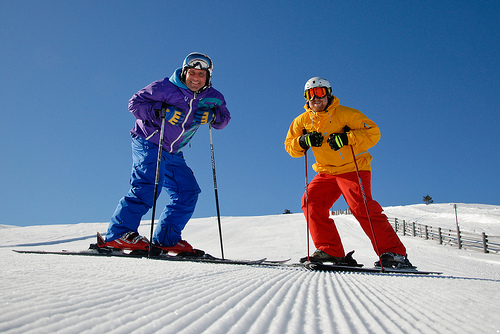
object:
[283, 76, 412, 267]
man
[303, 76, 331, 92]
helmet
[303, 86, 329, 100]
protective goggles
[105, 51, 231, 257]
man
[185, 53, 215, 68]
goggles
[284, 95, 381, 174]
jacket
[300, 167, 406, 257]
ski pants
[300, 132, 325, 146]
gloves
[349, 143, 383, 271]
ski pole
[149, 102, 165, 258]
ski poles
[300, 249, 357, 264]
boots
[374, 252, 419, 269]
skis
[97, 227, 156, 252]
boots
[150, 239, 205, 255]
skis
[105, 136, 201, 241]
ski pants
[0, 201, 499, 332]
snow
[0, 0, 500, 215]
sky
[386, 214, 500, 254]
fence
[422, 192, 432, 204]
tree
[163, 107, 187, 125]
gloves